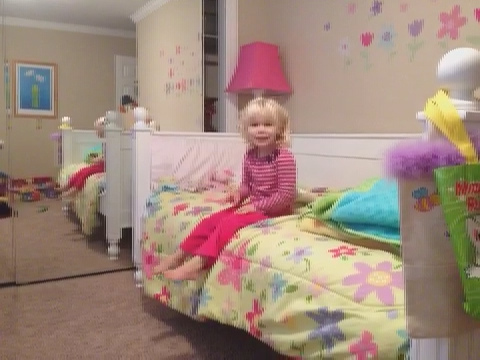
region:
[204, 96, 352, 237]
Blonde haired little girl.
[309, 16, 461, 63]
Flowers on the wall.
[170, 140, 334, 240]
Pink striped shirt.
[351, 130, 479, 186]
Purple dyed feather trim.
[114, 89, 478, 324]
White day bed.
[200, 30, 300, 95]
Pink lamp shade.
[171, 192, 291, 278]
Bright pink pants.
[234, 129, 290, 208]
child wearing a pink striped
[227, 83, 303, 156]
child with blond hair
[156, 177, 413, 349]
yellow blanket on the bed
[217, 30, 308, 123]
Pink lamp on the table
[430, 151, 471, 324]
Green bag on the bed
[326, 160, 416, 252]
blue blanket on the bed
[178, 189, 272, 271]
child wearing pink pants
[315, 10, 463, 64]
flowers on the wall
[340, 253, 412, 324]
purple flower on the blanket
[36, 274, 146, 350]
carpet on the floor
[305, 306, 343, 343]
a blue flower on the blanket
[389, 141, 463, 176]
purple fuzz on the bag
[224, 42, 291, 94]
a pink lamp shade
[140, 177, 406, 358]
the bedspread is yellow with flowers on it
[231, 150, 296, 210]
a pink striped shirt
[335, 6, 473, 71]
flower stickers on the wall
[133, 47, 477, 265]
white framed bed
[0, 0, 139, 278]
reflection in the mirror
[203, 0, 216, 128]
the closet door is open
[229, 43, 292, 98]
a pink lamp behind a little girl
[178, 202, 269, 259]
pink pants on a little girl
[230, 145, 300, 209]
a pink striped shirt on a little girl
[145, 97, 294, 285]
a little blond girl sitting on a bed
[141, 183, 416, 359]
a yellow floral comforter on a bed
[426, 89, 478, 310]
a green bag with a yellow handle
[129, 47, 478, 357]
a white twin bed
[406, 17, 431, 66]
a purple flower painted on a wall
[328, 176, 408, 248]
a blue blanket on a bed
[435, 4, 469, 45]
a pink flower painted on a wall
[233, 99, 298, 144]
The little girl has light hair.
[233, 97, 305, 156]
The little girls hair is blonde.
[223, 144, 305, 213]
The girls shirt is striped.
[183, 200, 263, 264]
The girls pants are pink.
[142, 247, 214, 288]
The girl is barefoot.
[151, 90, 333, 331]
The girl is sitting on her bed.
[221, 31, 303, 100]
The lamp has a pink shade.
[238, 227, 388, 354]
The bedspread is yellow.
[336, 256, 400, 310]
The bedspread has purple flower.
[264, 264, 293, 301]
The bedspread has a blue flower.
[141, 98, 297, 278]
girl sitting on the bed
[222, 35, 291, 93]
pink lampshade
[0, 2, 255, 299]
mirror behind the girl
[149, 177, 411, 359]
yellow bedspread with flower print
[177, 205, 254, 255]
pink pants the girl is wearing